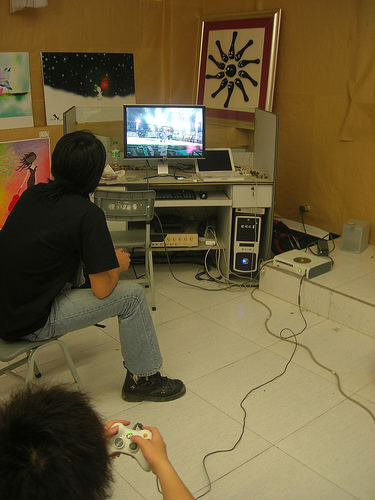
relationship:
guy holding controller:
[0, 371, 201, 499] [103, 422, 159, 474]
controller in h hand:
[103, 422, 159, 474] [99, 419, 130, 437]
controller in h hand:
[103, 422, 159, 474] [129, 425, 166, 473]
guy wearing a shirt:
[0, 125, 188, 404] [0, 181, 121, 341]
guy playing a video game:
[0, 125, 188, 404] [124, 103, 207, 158]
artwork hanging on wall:
[194, 7, 282, 130] [1, 1, 371, 245]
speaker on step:
[340, 217, 371, 253] [258, 233, 374, 338]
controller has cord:
[101, 419, 152, 470] [132, 262, 311, 497]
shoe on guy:
[116, 364, 187, 404] [0, 125, 188, 404]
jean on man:
[29, 275, 173, 376] [9, 118, 205, 418]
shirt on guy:
[8, 188, 124, 273] [0, 125, 188, 404]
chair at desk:
[90, 188, 163, 311] [82, 153, 285, 290]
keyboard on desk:
[136, 188, 197, 202] [56, 101, 284, 293]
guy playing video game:
[0, 371, 201, 499] [124, 103, 207, 158]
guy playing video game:
[0, 125, 188, 404] [124, 103, 207, 158]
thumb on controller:
[124, 428, 147, 453] [103, 417, 155, 476]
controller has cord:
[103, 421, 158, 474] [226, 376, 276, 462]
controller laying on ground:
[103, 421, 158, 474] [168, 338, 346, 488]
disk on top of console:
[291, 253, 314, 270] [270, 242, 341, 289]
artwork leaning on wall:
[40, 51, 136, 125] [1, 1, 371, 245]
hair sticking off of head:
[0, 375, 121, 499] [2, 382, 112, 496]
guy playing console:
[0, 371, 201, 499] [272, 249, 336, 280]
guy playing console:
[0, 125, 188, 404] [272, 249, 336, 280]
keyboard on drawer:
[136, 188, 199, 204] [154, 189, 232, 207]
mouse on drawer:
[199, 191, 207, 200] [155, 189, 232, 207]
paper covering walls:
[272, 4, 372, 228] [1, 1, 373, 243]